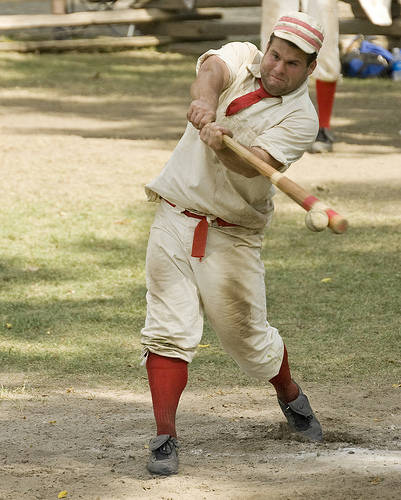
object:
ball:
[304, 204, 330, 232]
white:
[315, 213, 323, 221]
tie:
[223, 77, 277, 118]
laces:
[155, 438, 180, 460]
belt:
[157, 192, 267, 263]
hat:
[272, 11, 326, 56]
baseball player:
[138, 10, 326, 474]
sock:
[268, 340, 300, 402]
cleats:
[276, 378, 323, 444]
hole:
[268, 422, 365, 445]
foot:
[276, 379, 326, 444]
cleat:
[145, 432, 181, 474]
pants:
[138, 193, 285, 382]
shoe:
[146, 434, 178, 473]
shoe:
[277, 378, 322, 442]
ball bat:
[221, 132, 350, 235]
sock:
[146, 353, 189, 438]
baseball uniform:
[140, 10, 326, 381]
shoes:
[146, 431, 181, 473]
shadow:
[0, 296, 67, 340]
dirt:
[0, 384, 400, 498]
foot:
[146, 429, 180, 477]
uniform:
[125, 39, 320, 384]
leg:
[140, 248, 204, 440]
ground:
[0, 51, 400, 499]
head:
[260, 12, 327, 95]